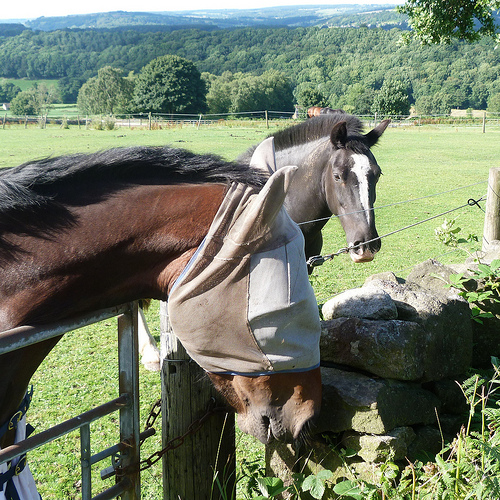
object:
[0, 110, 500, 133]
fence in field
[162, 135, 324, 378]
mask on horse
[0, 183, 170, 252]
hide is brown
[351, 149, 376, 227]
hide is white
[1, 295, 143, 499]
fence has gate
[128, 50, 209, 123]
tree in background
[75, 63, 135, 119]
tree in background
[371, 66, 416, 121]
tree is green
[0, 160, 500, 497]
fence next to horse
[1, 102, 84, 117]
grass is green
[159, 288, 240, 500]
post is wooden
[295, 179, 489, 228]
wire is silver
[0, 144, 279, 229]
mane is black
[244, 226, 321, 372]
material is cloth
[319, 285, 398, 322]
rock beside horse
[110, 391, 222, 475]
chain is on fence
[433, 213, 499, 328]
plant is green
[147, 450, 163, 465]
chain has link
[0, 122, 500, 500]
field is green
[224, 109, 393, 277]
horse is standing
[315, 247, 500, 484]
wall is rocky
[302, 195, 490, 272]
wire is attached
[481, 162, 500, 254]
post is wooden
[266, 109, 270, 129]
post is wooden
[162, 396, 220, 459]
chain on post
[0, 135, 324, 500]
horse has ear